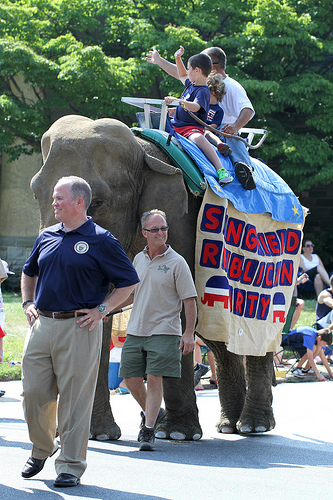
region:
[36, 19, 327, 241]
3 people riding an elephant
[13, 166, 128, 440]
a man in a blue polo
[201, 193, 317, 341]
a sign advertising the republican party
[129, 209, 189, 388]
a man in a beige polo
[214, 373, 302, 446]
2 elephant feet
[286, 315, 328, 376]
a young boy watching a parade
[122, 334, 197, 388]
a pair of green shorts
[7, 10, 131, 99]
leafy green trees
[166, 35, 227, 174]
a young boy waving to a crowd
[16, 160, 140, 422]
a politician walking in a parade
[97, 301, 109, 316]
Watch on mans wrist.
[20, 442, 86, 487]
A black pair of dress shoes.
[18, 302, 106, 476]
Tan pair of slacks.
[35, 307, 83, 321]
A brown leather belt.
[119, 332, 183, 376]
Green pair of shorts.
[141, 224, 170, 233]
The sunglasses on mans face.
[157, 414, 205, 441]
The elephant foot.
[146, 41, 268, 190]
people riding on an elephant.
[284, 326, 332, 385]
A kid bending over.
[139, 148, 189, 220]
The ear of the elephant.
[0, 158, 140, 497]
White male posing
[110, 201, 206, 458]
White male walking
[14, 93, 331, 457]
White male in tan shirt leading a elephant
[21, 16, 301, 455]
Elephant carrying kids around on its back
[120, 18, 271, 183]
Young family riding a elephant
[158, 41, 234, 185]
Young male sitting on a elephant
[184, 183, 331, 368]
Sign draped over an elephant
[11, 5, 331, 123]
Green leafy trees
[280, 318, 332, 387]
Young male bent over picking something up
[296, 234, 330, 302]
Woman with sunglasses sitting in a chair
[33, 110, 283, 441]
large grey walking elephant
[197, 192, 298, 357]
republican party banner on elephant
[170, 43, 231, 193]
young boy in blue tee shirt and red shorts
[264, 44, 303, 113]
green leaves on trees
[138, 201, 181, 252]
man wearing tinted glasses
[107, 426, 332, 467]
shadow of elephant on pavement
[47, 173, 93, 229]
man's face with pink splotches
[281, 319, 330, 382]
boy in blue tee shirt bending over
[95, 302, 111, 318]
man's wristwatch on left wrist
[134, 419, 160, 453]
black lace up sneaker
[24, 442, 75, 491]
Person wearing dark shoes.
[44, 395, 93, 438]
Person wearing tan pants.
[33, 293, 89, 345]
Person wearing brown belt.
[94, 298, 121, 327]
Watch on person's wrist.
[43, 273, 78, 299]
Person wearing blue shirt.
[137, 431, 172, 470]
Person wearing dark shoes.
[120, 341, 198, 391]
Person wearing green shorts.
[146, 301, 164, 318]
Person wearing tan shorts.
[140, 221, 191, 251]
Glasses on person's face.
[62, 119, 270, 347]
Large elephant beside people walking.